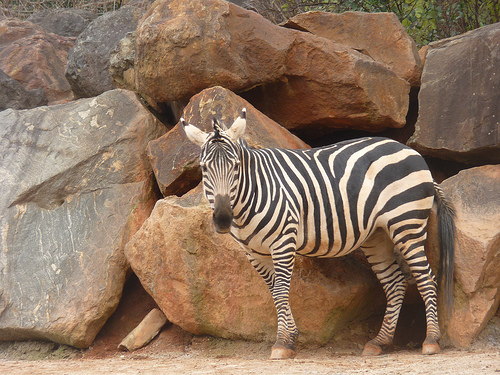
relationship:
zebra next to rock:
[180, 107, 458, 359] [0, 87, 170, 350]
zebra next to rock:
[180, 107, 458, 359] [106, 1, 412, 137]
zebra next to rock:
[180, 107, 458, 359] [407, 23, 500, 160]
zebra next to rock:
[180, 107, 458, 359] [146, 86, 314, 197]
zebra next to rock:
[180, 107, 458, 359] [123, 178, 386, 347]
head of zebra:
[200, 130, 242, 235] [180, 107, 458, 359]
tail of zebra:
[433, 180, 461, 321] [180, 107, 458, 359]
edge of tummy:
[295, 247, 361, 257] [296, 226, 375, 257]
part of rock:
[183, 85, 314, 150] [146, 86, 314, 197]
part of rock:
[125, 179, 279, 345] [123, 178, 386, 347]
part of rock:
[145, 121, 203, 199] [146, 86, 314, 197]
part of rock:
[289, 251, 385, 349] [123, 178, 386, 347]